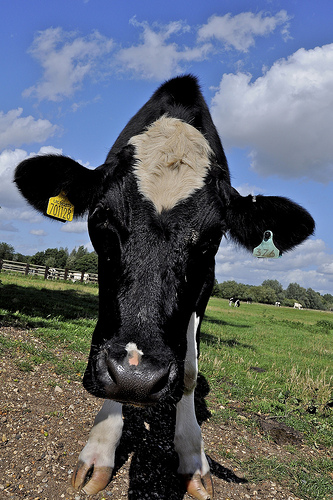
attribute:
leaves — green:
[213, 282, 330, 301]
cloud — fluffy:
[259, 100, 326, 142]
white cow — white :
[292, 300, 303, 310]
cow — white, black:
[15, 76, 308, 497]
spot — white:
[129, 119, 211, 207]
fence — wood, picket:
[2, 257, 85, 282]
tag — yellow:
[45, 191, 74, 221]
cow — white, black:
[17, 79, 294, 440]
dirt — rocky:
[33, 382, 98, 457]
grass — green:
[255, 300, 304, 351]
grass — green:
[1, 270, 330, 496]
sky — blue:
[0, 0, 332, 295]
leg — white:
[74, 397, 124, 468]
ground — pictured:
[4, 270, 330, 498]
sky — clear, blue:
[205, 3, 308, 76]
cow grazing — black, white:
[231, 294, 241, 306]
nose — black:
[97, 340, 186, 395]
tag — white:
[252, 230, 280, 260]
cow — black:
[138, 217, 177, 302]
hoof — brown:
[184, 467, 208, 495]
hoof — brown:
[78, 459, 102, 489]